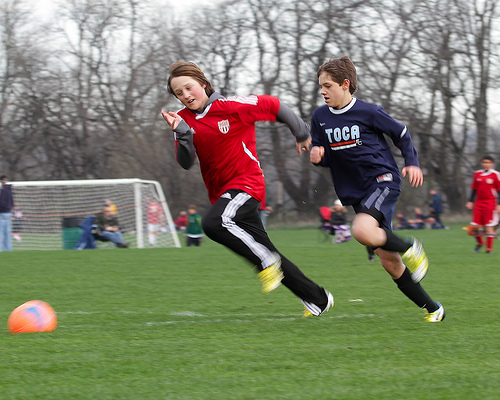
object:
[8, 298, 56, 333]
soccer ball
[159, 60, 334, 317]
boy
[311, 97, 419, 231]
jersey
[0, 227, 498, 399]
field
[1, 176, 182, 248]
soccer net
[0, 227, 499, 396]
grass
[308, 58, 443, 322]
boy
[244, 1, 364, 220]
tree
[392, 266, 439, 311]
sock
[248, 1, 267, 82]
branch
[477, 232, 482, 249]
sock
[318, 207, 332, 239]
chair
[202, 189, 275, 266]
leg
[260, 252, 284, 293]
shoe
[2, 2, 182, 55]
sky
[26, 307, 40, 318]
spot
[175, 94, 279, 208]
shirt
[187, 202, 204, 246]
person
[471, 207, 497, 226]
shorts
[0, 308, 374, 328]
line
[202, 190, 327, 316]
pants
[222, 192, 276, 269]
stripe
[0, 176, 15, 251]
man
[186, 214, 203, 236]
shirt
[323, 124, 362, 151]
logo